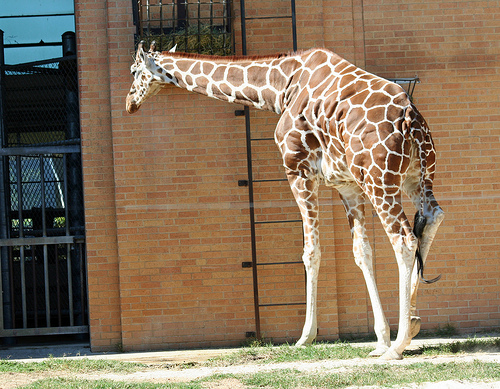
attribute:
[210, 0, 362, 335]
ladder — metal, black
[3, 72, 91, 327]
fence — side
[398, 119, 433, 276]
tail — giraffe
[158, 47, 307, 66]
mane — giraffe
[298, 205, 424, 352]
legs — white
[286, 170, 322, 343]
leg — giraffe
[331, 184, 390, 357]
leg — giraffe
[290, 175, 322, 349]
leg — giraffe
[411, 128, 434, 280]
tail — white, brown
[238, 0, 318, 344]
ladder — metal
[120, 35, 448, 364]
giraffe — spots, head, brown, white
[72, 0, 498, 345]
wall — brick, orange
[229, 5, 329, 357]
ladder — black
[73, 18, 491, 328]
building — brick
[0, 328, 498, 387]
grass — sparse, green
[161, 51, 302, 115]
neck — giraffe's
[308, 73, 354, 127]
spots — brown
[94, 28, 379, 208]
giraffe — neck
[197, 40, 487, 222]
giraffe — solitary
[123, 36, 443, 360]
head — horns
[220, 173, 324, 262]
ladder — black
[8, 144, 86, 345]
barrier — metal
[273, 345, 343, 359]
grass — dry, green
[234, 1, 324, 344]
escape — part, fire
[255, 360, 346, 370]
patch — bare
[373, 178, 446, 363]
legs — back, giraffe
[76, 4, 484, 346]
building — bricks